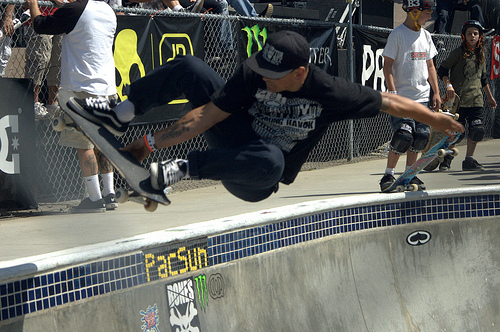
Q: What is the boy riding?
A: A skateboard.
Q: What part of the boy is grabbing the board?
A: Hand.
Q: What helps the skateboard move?
A: Wheels.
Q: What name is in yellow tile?
A: PacSun.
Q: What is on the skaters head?
A: A black hat.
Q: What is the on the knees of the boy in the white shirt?
A: Knee pads.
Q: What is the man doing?
A: Stunk skating.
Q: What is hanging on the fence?
A: A banner.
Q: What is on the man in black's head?
A: A hat.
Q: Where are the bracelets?
A: On the wrist.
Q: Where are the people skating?
A: In a pool.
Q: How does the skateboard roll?
A: On wheels.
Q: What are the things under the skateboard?
A: Wheels.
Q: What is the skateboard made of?
A: Wood.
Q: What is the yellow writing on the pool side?
A: PacSun.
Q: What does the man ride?
A: A skateboard.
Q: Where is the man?
A: In a skate park.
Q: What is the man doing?
A: Skateboarding.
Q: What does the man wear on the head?
A: A hat.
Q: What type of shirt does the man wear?
A: A t shirt.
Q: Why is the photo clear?
A: Its during the day.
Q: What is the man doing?
A: Skating.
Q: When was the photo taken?
A: Daytime.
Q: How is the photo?
A: Clear.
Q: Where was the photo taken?
A: At a skateboard park.